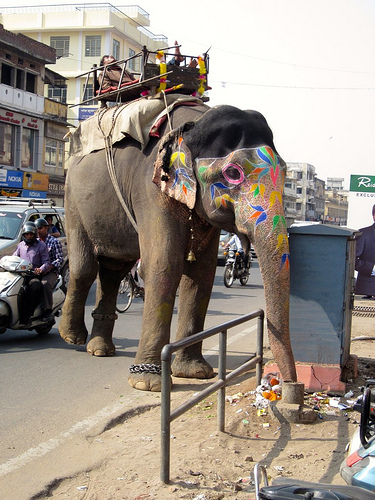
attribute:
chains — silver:
[127, 363, 161, 374]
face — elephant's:
[218, 125, 293, 236]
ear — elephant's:
[149, 131, 199, 213]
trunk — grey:
[251, 222, 295, 382]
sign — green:
[349, 174, 373, 193]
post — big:
[284, 214, 363, 394]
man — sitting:
[12, 220, 51, 304]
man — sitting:
[36, 217, 62, 278]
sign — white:
[346, 174, 374, 296]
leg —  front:
[128, 191, 191, 391]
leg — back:
[86, 257, 138, 357]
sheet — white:
[100, 106, 141, 146]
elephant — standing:
[60, 106, 289, 292]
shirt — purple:
[14, 240, 52, 277]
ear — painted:
[147, 143, 203, 201]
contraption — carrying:
[60, 39, 214, 110]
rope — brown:
[93, 99, 141, 240]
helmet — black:
[21, 218, 36, 233]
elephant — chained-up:
[58, 102, 296, 389]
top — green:
[350, 171, 371, 207]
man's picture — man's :
[353, 200, 372, 294]